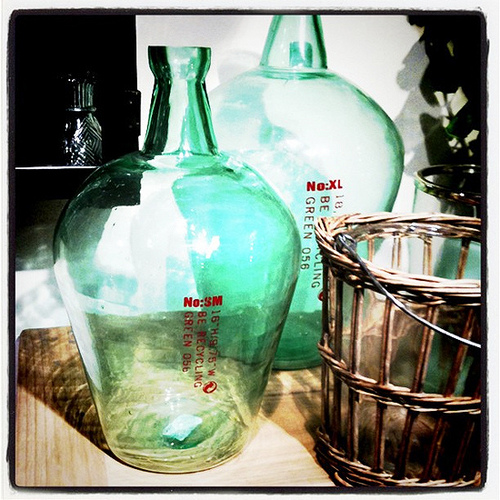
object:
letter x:
[329, 180, 337, 190]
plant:
[407, 14, 486, 216]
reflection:
[67, 151, 196, 257]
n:
[307, 181, 315, 191]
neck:
[141, 77, 214, 153]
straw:
[330, 378, 343, 448]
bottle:
[53, 43, 299, 475]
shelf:
[14, 157, 101, 173]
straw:
[370, 402, 388, 471]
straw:
[420, 412, 448, 482]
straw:
[453, 239, 471, 281]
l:
[338, 180, 343, 189]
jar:
[217, 11, 410, 376]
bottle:
[208, 14, 405, 370]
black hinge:
[112, 90, 141, 136]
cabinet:
[14, 13, 143, 201]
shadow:
[348, 40, 429, 86]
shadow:
[17, 329, 109, 452]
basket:
[311, 212, 481, 489]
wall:
[132, 18, 456, 310]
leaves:
[406, 12, 481, 164]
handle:
[338, 237, 480, 352]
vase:
[61, 72, 106, 166]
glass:
[406, 164, 483, 281]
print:
[183, 296, 222, 394]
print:
[301, 179, 345, 288]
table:
[16, 198, 455, 491]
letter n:
[183, 297, 192, 308]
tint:
[178, 48, 303, 417]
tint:
[347, 81, 403, 211]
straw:
[376, 301, 394, 388]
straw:
[409, 305, 440, 393]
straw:
[346, 284, 363, 375]